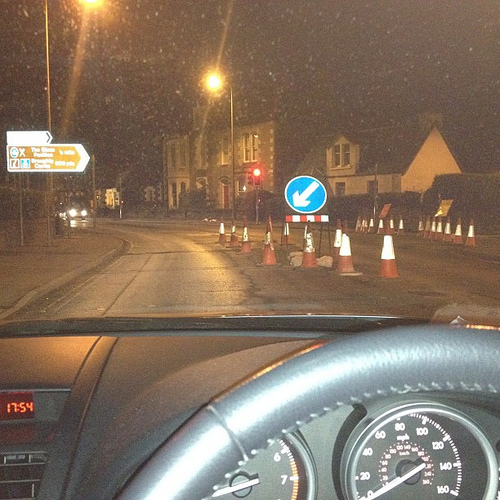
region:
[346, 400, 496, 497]
the speedometer on the car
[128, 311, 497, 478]
the gray steering wheel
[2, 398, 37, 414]
the digital clock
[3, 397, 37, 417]
the time in red digital numbers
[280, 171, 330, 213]
the blue circle sign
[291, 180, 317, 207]
the white arrow on the blue sign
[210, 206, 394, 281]
the group of cones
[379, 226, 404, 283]
the orange cone with reflector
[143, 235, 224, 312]
the dark gray pavement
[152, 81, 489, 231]
the buildings on the side of the road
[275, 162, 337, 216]
blue and white sign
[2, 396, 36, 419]
digital clock indicates it's 17:54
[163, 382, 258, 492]
light shining on the steering wheel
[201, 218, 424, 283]
row of orange and white traffic cones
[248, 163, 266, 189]
traffic light shining red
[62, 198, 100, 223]
car driving down the road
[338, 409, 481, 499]
speedometer showing the car is going 0 MPH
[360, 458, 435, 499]
needle of the speedometer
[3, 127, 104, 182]
sign on the side of the road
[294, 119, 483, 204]
white building with a black roof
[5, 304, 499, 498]
The inside dash of a vehicle.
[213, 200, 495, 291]
Orange cones line the street.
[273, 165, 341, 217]
The sign is round.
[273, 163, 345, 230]
The sign is green.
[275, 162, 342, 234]
There's an arrow on the sign.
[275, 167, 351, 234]
The arrow points downward.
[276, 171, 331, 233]
The arrow is white.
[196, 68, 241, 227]
The streetlight is on a pole.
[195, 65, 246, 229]
The streetlight is on.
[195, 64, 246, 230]
The pole is straight.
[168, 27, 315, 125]
lights reflecting in a night sky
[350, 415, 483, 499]
speedometer in a car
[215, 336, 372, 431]
a gray steering wheel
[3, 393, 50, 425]
the time in red numbers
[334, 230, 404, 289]
white and orange Traffic safety cones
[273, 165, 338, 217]
an blue sign with a white arrowfacing down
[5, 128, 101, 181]
white and yellow street signs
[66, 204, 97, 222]
headlights of an on coming car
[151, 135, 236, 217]
A brick building with white trimmed windows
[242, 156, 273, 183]
a red signal light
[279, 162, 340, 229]
white and blue circular traffic sign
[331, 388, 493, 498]
speedometer ranges from 0 to 160 mph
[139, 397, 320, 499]
tachometer shows rotations per minute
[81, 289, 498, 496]
black steering wheel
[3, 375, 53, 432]
red digital display reads 17:54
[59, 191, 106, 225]
oncoming vehicle with its headlights on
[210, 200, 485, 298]
many orange traffic cones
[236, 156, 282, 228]
red traffic light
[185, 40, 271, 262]
illuminated street light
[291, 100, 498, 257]
house on the side of the road